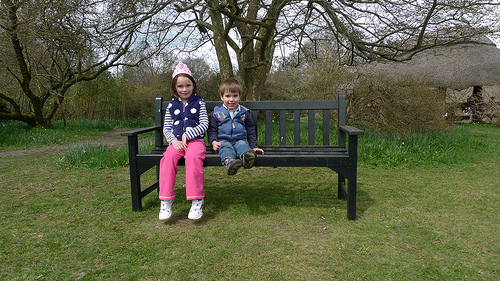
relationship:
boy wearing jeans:
[213, 83, 261, 174] [217, 138, 249, 163]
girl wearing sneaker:
[156, 61, 208, 223] [185, 199, 205, 220]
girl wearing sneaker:
[156, 61, 208, 223] [157, 201, 174, 218]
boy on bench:
[214, 78, 263, 160] [262, 95, 422, 213]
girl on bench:
[157, 51, 210, 208] [262, 95, 422, 213]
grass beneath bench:
[1, 105, 498, 280] [115, 89, 364, 219]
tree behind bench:
[69, 13, 407, 98] [126, 99, 356, 230]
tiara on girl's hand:
[169, 56, 191, 78] [156, 51, 207, 199]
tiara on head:
[169, 62, 193, 78] [171, 74, 196, 99]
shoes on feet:
[150, 192, 258, 240] [151, 197, 208, 227]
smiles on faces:
[174, 92, 239, 108] [165, 70, 252, 108]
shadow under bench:
[151, 167, 376, 225] [106, 75, 387, 229]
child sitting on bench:
[156, 60, 209, 222] [115, 89, 364, 219]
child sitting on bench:
[208, 80, 264, 173] [115, 89, 364, 219]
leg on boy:
[234, 137, 257, 168] [208, 66, 275, 203]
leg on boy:
[219, 139, 242, 175] [208, 66, 275, 203]